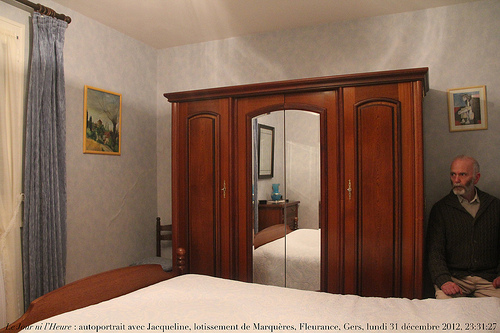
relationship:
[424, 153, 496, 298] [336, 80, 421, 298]
man is seated beside door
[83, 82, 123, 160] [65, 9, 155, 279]
frame on wall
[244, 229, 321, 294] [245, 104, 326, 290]
bed through mirror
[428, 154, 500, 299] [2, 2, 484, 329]
man in bedroom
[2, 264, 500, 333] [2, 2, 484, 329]
bed in bedroom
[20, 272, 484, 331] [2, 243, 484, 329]
bedspread on bed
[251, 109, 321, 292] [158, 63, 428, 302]
mirror in cupboard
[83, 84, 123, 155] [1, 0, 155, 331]
frame on wall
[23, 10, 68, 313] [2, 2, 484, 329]
curtain in bedroom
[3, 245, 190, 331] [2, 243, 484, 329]
foot board on bed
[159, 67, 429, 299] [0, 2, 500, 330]
cupboard in bedroom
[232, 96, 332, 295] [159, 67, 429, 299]
mirror on front of cupboard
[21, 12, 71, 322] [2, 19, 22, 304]
curtain at window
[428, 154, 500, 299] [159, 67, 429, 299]
man next to cupboard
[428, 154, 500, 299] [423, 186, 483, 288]
man in sweater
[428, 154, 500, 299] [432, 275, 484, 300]
man in pants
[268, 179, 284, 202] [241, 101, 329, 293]
vase in mirror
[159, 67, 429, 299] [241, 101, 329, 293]
cupboard has mirror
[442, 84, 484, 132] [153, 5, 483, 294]
picture on wall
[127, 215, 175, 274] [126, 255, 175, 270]
chair with cushion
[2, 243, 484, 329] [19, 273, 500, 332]
bed with bedspread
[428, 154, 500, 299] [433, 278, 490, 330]
man in a chair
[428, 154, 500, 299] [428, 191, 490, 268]
man with sweater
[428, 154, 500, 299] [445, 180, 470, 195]
man with facial hair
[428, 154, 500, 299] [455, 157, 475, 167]
man with hair line